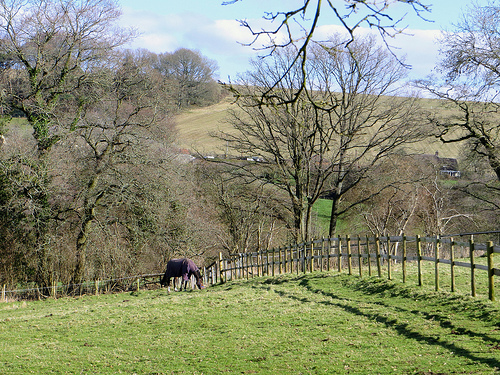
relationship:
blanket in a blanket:
[167, 258, 205, 294] [168, 254, 204, 284]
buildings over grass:
[199, 151, 281, 166] [19, 264, 497, 373]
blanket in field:
[167, 258, 205, 294] [2, 250, 499, 373]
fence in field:
[0, 229, 500, 303] [2, 250, 499, 373]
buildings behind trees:
[169, 147, 192, 162] [248, 60, 423, 230]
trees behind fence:
[251, 8, 456, 223] [194, 227, 484, 308]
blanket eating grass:
[167, 258, 205, 294] [175, 294, 267, 336]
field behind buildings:
[176, 72, 496, 189] [169, 147, 192, 162]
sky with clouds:
[3, 2, 497, 89] [184, 17, 478, 57]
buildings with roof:
[169, 147, 192, 162] [382, 151, 457, 171]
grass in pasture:
[19, 264, 497, 373] [13, 269, 485, 374]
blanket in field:
[167, 258, 205, 294] [8, 201, 496, 374]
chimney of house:
[433, 147, 439, 157] [394, 122, 475, 219]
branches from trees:
[95, 179, 128, 228] [0, 0, 193, 291]